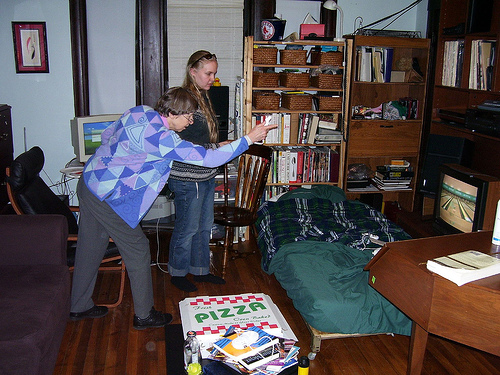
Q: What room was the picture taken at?
A: It was taken at the bedroom.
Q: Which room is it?
A: It is a bedroom.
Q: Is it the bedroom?
A: Yes, it is the bedroom.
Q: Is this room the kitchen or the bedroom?
A: It is the bedroom.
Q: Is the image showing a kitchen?
A: No, the picture is showing a bedroom.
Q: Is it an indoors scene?
A: Yes, it is indoors.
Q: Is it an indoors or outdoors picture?
A: It is indoors.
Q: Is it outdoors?
A: No, it is indoors.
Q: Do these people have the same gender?
A: Yes, all the people are female.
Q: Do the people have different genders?
A: No, all the people are female.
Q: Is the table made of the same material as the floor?
A: Yes, both the table and the floor are made of wood.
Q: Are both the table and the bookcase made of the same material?
A: Yes, both the table and the bookcase are made of wood.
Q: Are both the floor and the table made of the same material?
A: Yes, both the floor and the table are made of wood.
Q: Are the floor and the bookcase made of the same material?
A: Yes, both the floor and the bookcase are made of wood.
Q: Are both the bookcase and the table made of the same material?
A: Yes, both the bookcase and the table are made of wood.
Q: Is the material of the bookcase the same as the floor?
A: Yes, both the bookcase and the floor are made of wood.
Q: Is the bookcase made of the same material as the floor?
A: Yes, both the bookcase and the floor are made of wood.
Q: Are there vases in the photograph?
A: No, there are no vases.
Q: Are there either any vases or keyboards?
A: No, there are no vases or keyboards.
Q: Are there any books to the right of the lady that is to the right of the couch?
A: Yes, there are books to the right of the lady.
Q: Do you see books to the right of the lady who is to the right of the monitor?
A: Yes, there are books to the right of the lady.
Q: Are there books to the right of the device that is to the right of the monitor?
A: Yes, there are books to the right of the controller.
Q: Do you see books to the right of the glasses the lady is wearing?
A: Yes, there are books to the right of the glasses.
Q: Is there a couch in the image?
A: Yes, there is a couch.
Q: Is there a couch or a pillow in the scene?
A: Yes, there is a couch.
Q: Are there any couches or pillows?
A: Yes, there is a couch.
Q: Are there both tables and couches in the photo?
A: Yes, there are both a couch and a table.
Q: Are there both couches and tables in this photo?
A: Yes, there are both a couch and a table.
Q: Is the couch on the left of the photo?
A: Yes, the couch is on the left of the image.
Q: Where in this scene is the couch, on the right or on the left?
A: The couch is on the left of the image.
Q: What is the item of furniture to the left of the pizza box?
A: The piece of furniture is a couch.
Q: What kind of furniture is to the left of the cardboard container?
A: The piece of furniture is a couch.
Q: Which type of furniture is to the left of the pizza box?
A: The piece of furniture is a couch.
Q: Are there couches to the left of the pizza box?
A: Yes, there is a couch to the left of the pizza box.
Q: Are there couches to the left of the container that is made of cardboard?
A: Yes, there is a couch to the left of the pizza box.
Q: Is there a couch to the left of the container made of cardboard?
A: Yes, there is a couch to the left of the pizza box.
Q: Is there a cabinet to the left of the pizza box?
A: No, there is a couch to the left of the pizza box.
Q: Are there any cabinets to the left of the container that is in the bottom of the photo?
A: No, there is a couch to the left of the pizza box.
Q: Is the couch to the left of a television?
A: No, the couch is to the left of the pizza box.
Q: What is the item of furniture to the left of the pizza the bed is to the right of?
A: The piece of furniture is a couch.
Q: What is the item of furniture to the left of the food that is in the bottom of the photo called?
A: The piece of furniture is a couch.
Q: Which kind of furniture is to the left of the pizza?
A: The piece of furniture is a couch.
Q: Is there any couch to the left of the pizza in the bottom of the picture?
A: Yes, there is a couch to the left of the pizza.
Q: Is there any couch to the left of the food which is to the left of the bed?
A: Yes, there is a couch to the left of the pizza.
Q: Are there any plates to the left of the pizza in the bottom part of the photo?
A: No, there is a couch to the left of the pizza.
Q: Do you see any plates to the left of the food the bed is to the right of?
A: No, there is a couch to the left of the pizza.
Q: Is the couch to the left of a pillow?
A: No, the couch is to the left of the pizza.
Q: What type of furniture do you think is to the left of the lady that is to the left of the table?
A: The piece of furniture is a couch.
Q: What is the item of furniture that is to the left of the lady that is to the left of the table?
A: The piece of furniture is a couch.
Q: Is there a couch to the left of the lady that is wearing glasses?
A: Yes, there is a couch to the left of the lady.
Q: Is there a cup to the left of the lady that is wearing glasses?
A: No, there is a couch to the left of the lady.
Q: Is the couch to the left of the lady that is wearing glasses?
A: Yes, the couch is to the left of the lady.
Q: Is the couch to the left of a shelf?
A: No, the couch is to the left of the lady.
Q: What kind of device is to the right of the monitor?
A: The device is a controller.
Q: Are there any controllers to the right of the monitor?
A: Yes, there is a controller to the right of the monitor.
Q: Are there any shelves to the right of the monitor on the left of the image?
A: No, there is a controller to the right of the monitor.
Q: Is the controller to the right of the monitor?
A: Yes, the controller is to the right of the monitor.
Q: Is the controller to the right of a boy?
A: No, the controller is to the right of the monitor.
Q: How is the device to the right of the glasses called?
A: The device is a controller.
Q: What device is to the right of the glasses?
A: The device is a controller.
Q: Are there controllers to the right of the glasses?
A: Yes, there is a controller to the right of the glasses.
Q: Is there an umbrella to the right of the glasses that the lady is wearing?
A: No, there is a controller to the right of the glasses.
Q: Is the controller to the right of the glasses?
A: Yes, the controller is to the right of the glasses.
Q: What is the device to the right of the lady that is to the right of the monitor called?
A: The device is a controller.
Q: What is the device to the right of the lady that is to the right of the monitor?
A: The device is a controller.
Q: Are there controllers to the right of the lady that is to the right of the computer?
A: Yes, there is a controller to the right of the lady.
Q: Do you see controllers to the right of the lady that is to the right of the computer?
A: Yes, there is a controller to the right of the lady.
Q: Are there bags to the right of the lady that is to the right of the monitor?
A: No, there is a controller to the right of the lady.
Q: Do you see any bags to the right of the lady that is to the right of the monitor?
A: No, there is a controller to the right of the lady.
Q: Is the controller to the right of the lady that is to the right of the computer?
A: Yes, the controller is to the right of the lady.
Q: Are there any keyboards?
A: No, there are no keyboards.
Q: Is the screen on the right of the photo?
A: Yes, the screen is on the right of the image.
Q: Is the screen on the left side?
A: No, the screen is on the right of the image.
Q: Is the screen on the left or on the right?
A: The screen is on the right of the image.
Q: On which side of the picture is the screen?
A: The screen is on the right of the image.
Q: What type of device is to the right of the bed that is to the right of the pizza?
A: The device is a screen.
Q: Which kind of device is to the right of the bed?
A: The device is a screen.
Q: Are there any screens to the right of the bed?
A: Yes, there is a screen to the right of the bed.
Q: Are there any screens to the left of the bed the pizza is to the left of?
A: No, the screen is to the right of the bed.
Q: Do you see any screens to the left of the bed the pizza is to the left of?
A: No, the screen is to the right of the bed.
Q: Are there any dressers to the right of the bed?
A: No, there is a screen to the right of the bed.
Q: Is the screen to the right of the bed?
A: Yes, the screen is to the right of the bed.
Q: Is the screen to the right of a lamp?
A: No, the screen is to the right of the bed.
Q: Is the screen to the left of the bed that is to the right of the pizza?
A: No, the screen is to the right of the bed.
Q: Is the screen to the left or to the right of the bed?
A: The screen is to the right of the bed.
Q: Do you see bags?
A: No, there are no bags.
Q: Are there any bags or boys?
A: No, there are no bags or boys.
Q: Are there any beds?
A: Yes, there is a bed.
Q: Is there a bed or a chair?
A: Yes, there is a bed.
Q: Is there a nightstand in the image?
A: No, there are no nightstands.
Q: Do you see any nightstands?
A: No, there are no nightstands.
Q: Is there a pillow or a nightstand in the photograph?
A: No, there are no nightstands or pillows.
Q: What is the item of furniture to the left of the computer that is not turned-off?
A: The piece of furniture is a bed.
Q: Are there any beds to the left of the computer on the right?
A: Yes, there is a bed to the left of the computer.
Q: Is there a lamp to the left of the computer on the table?
A: No, there is a bed to the left of the computer.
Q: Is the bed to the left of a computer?
A: Yes, the bed is to the left of a computer.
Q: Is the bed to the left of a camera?
A: No, the bed is to the left of a computer.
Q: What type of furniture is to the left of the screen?
A: The piece of furniture is a bed.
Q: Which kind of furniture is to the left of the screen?
A: The piece of furniture is a bed.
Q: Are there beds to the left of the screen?
A: Yes, there is a bed to the left of the screen.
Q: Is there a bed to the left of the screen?
A: Yes, there is a bed to the left of the screen.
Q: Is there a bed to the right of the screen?
A: No, the bed is to the left of the screen.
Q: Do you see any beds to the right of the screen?
A: No, the bed is to the left of the screen.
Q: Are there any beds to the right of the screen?
A: No, the bed is to the left of the screen.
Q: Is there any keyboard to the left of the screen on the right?
A: No, there is a bed to the left of the screen.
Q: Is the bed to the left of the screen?
A: Yes, the bed is to the left of the screen.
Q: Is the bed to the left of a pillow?
A: No, the bed is to the left of the screen.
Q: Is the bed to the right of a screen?
A: No, the bed is to the left of a screen.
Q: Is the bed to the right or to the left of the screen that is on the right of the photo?
A: The bed is to the left of the screen.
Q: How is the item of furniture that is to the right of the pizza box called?
A: The piece of furniture is a bed.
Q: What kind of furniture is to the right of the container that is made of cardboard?
A: The piece of furniture is a bed.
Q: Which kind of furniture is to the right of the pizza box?
A: The piece of furniture is a bed.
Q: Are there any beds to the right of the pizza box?
A: Yes, there is a bed to the right of the pizza box.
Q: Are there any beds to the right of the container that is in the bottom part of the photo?
A: Yes, there is a bed to the right of the pizza box.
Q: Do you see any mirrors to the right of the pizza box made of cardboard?
A: No, there is a bed to the right of the pizza box.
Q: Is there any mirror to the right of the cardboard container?
A: No, there is a bed to the right of the pizza box.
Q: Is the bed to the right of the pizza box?
A: Yes, the bed is to the right of the pizza box.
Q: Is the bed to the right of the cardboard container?
A: Yes, the bed is to the right of the pizza box.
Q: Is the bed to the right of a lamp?
A: No, the bed is to the right of the pizza box.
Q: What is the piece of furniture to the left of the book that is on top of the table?
A: The piece of furniture is a bed.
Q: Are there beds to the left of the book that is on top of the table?
A: Yes, there is a bed to the left of the book.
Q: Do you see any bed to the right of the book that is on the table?
A: No, the bed is to the left of the book.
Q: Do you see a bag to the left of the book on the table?
A: No, there is a bed to the left of the book.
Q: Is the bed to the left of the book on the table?
A: Yes, the bed is to the left of the book.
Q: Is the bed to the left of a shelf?
A: No, the bed is to the left of the book.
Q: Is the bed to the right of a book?
A: No, the bed is to the left of a book.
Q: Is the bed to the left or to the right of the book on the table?
A: The bed is to the left of the book.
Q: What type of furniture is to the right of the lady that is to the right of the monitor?
A: The piece of furniture is a bed.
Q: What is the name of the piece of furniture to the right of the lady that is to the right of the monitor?
A: The piece of furniture is a bed.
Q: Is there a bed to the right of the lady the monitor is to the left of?
A: Yes, there is a bed to the right of the lady.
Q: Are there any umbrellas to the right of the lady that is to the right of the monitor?
A: No, there is a bed to the right of the lady.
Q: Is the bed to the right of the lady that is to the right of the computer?
A: Yes, the bed is to the right of the lady.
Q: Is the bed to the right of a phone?
A: No, the bed is to the right of the lady.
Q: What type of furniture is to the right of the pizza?
A: The piece of furniture is a bed.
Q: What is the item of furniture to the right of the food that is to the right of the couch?
A: The piece of furniture is a bed.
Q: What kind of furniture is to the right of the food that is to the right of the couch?
A: The piece of furniture is a bed.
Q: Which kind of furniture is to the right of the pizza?
A: The piece of furniture is a bed.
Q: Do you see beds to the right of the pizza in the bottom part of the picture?
A: Yes, there is a bed to the right of the pizza.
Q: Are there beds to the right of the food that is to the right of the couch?
A: Yes, there is a bed to the right of the pizza.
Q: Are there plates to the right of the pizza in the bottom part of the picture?
A: No, there is a bed to the right of the pizza.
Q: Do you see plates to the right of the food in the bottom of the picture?
A: No, there is a bed to the right of the pizza.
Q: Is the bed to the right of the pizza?
A: Yes, the bed is to the right of the pizza.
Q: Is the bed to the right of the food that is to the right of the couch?
A: Yes, the bed is to the right of the pizza.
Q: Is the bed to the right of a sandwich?
A: No, the bed is to the right of the pizza.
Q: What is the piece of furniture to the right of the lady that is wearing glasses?
A: The piece of furniture is a bed.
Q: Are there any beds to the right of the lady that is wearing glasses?
A: Yes, there is a bed to the right of the lady.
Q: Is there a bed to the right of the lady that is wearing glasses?
A: Yes, there is a bed to the right of the lady.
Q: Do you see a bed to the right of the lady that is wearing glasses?
A: Yes, there is a bed to the right of the lady.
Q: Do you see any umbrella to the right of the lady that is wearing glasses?
A: No, there is a bed to the right of the lady.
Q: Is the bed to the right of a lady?
A: Yes, the bed is to the right of a lady.